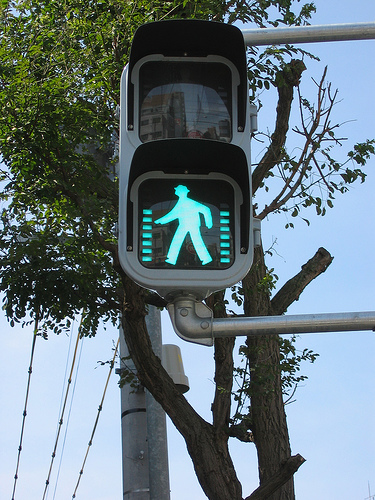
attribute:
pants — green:
[164, 224, 215, 267]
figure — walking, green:
[157, 184, 216, 266]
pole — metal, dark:
[171, 295, 374, 343]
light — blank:
[113, 21, 255, 287]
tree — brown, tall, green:
[0, 1, 375, 499]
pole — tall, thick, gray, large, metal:
[116, 288, 171, 498]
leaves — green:
[0, 1, 372, 426]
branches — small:
[250, 47, 371, 226]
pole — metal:
[241, 20, 373, 52]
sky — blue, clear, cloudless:
[0, 1, 374, 499]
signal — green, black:
[133, 171, 241, 276]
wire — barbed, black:
[17, 357, 110, 495]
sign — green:
[140, 182, 233, 268]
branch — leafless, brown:
[267, 239, 342, 329]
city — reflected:
[141, 88, 233, 141]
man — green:
[165, 183, 201, 269]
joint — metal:
[168, 295, 214, 347]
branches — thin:
[254, 64, 372, 228]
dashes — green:
[138, 206, 156, 266]